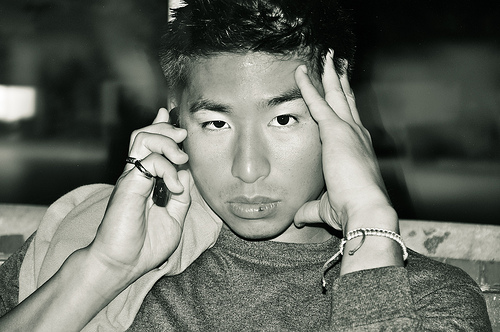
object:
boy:
[0, 0, 499, 331]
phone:
[151, 108, 181, 208]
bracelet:
[337, 228, 408, 262]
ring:
[135, 160, 153, 179]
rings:
[126, 157, 136, 164]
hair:
[160, 0, 356, 85]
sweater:
[0, 229, 490, 331]